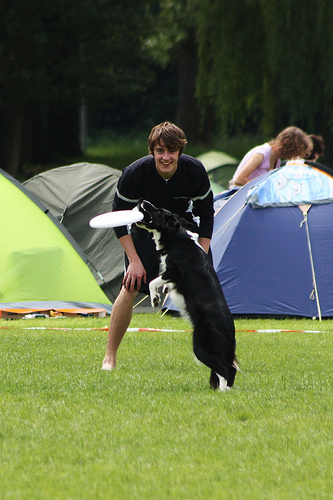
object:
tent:
[156, 162, 333, 318]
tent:
[18, 161, 171, 313]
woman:
[229, 126, 308, 188]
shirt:
[228, 141, 282, 187]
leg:
[105, 235, 143, 355]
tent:
[0, 167, 118, 316]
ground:
[0, 307, 333, 500]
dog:
[135, 198, 237, 391]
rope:
[0, 326, 332, 334]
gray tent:
[21, 161, 162, 315]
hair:
[148, 120, 186, 150]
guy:
[101, 121, 216, 371]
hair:
[147, 120, 186, 156]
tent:
[189, 149, 247, 189]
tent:
[18, 161, 161, 308]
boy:
[100, 121, 214, 368]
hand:
[121, 260, 147, 289]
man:
[101, 120, 215, 373]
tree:
[143, 0, 333, 169]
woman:
[230, 125, 313, 188]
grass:
[0, 131, 333, 500]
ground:
[0, 316, 333, 499]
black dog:
[134, 198, 237, 390]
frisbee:
[88, 210, 144, 230]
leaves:
[193, 4, 321, 122]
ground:
[0, 298, 333, 500]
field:
[1, 300, 333, 500]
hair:
[160, 219, 238, 382]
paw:
[149, 291, 161, 310]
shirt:
[111, 152, 214, 239]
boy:
[229, 126, 313, 189]